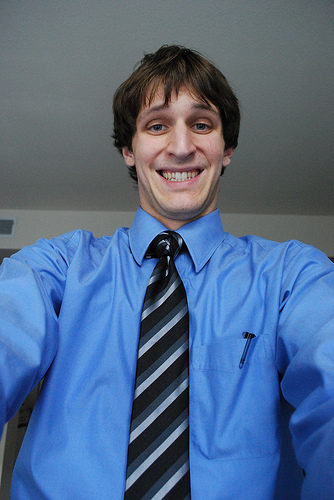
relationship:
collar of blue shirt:
[126, 203, 225, 275] [0, 206, 333, 498]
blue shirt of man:
[0, 206, 333, 498] [2, 45, 332, 498]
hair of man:
[109, 43, 240, 192] [2, 45, 332, 498]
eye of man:
[189, 116, 214, 134] [2, 45, 332, 498]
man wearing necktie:
[2, 45, 332, 498] [142, 206, 221, 370]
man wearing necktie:
[2, 45, 332, 498] [124, 230, 191, 498]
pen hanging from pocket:
[238, 327, 255, 370] [205, 328, 269, 374]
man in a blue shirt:
[2, 45, 332, 498] [0, 206, 333, 498]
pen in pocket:
[238, 327, 255, 368] [185, 336, 262, 458]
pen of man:
[238, 327, 255, 368] [2, 45, 332, 498]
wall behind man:
[3, 256, 333, 498] [2, 45, 332, 498]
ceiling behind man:
[2, 2, 330, 212] [2, 45, 332, 498]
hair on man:
[109, 43, 240, 151] [2, 45, 332, 498]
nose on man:
[142, 115, 205, 171] [2, 45, 332, 498]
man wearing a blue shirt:
[2, 45, 332, 498] [0, 206, 331, 498]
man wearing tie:
[2, 45, 332, 498] [120, 226, 192, 498]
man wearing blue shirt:
[2, 45, 332, 498] [0, 206, 333, 498]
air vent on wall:
[3, 211, 18, 236] [277, 136, 332, 236]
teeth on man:
[161, 169, 198, 183] [2, 45, 332, 498]